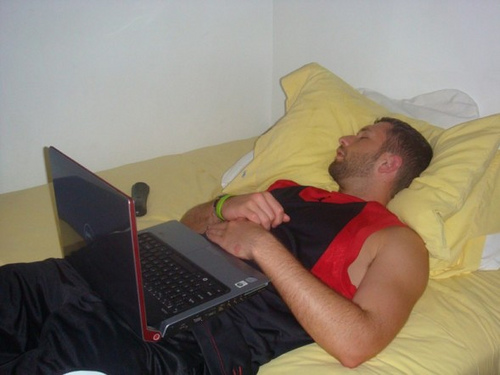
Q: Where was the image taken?
A: It was taken at the bedroom.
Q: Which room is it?
A: It is a bedroom.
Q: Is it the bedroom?
A: Yes, it is the bedroom.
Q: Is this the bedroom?
A: Yes, it is the bedroom.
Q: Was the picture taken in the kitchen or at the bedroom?
A: It was taken at the bedroom.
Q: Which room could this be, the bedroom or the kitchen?
A: It is the bedroom.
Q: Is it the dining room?
A: No, it is the bedroom.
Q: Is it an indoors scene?
A: Yes, it is indoors.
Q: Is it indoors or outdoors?
A: It is indoors.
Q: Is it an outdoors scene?
A: No, it is indoors.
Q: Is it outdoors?
A: No, it is indoors.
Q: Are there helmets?
A: No, there are no helmets.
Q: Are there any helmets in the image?
A: No, there are no helmets.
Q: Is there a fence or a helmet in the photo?
A: No, there are no helmets or fences.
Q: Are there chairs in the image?
A: No, there are no chairs.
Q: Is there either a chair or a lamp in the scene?
A: No, there are no chairs or lamps.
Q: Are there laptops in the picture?
A: Yes, there is a laptop.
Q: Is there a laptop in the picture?
A: Yes, there is a laptop.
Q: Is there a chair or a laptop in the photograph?
A: Yes, there is a laptop.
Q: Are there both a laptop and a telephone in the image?
A: No, there is a laptop but no phones.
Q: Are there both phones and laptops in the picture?
A: No, there is a laptop but no phones.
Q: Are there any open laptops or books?
A: Yes, there is an open laptop.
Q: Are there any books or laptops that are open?
A: Yes, the laptop is open.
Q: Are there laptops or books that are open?
A: Yes, the laptop is open.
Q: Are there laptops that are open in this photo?
A: Yes, there is an open laptop.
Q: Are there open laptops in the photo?
A: Yes, there is an open laptop.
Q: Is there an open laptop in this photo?
A: Yes, there is an open laptop.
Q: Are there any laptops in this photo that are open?
A: Yes, there is a laptop that is open.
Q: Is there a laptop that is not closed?
A: Yes, there is a open laptop.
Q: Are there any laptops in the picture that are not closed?
A: Yes, there is a open laptop.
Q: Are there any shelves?
A: No, there are no shelves.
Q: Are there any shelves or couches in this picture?
A: No, there are no shelves or couches.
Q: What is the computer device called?
A: The device is a laptop.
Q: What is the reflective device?
A: The device is a laptop.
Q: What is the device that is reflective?
A: The device is a laptop.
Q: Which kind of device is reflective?
A: The device is a laptop.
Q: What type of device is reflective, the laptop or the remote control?
A: The laptop is reflective.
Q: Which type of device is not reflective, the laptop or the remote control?
A: The remote control is not reflective.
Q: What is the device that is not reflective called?
A: The device is a remote control.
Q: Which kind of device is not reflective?
A: The device is a remote control.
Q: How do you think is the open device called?
A: The device is a laptop.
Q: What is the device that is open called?
A: The device is a laptop.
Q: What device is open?
A: The device is a laptop.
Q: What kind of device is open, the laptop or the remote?
A: The laptop is open.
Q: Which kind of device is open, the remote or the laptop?
A: The laptop is open.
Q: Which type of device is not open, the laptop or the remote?
A: The remote is not open.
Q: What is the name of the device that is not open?
A: The device is a remote control.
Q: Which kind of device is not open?
A: The device is a remote control.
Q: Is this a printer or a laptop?
A: This is a laptop.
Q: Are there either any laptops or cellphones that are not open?
A: No, there is a laptop but it is open.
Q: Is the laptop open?
A: Yes, the laptop is open.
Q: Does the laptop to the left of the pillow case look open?
A: Yes, the laptop is open.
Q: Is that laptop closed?
A: No, the laptop is open.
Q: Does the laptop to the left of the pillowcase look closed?
A: No, the laptop is open.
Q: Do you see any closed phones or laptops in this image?
A: No, there is a laptop but it is open.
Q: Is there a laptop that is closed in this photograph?
A: No, there is a laptop but it is open.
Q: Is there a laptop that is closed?
A: No, there is a laptop but it is open.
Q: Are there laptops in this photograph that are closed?
A: No, there is a laptop but it is open.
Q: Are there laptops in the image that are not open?
A: No, there is a laptop but it is open.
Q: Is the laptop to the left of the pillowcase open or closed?
A: The laptop computer is open.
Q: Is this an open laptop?
A: Yes, this is an open laptop.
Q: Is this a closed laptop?
A: No, this is an open laptop.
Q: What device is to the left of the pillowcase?
A: The device is a laptop.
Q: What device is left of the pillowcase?
A: The device is a laptop.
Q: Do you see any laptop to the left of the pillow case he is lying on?
A: Yes, there is a laptop to the left of the pillow case.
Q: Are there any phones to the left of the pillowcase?
A: No, there is a laptop to the left of the pillowcase.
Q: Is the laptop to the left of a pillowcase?
A: Yes, the laptop is to the left of a pillowcase.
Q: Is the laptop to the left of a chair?
A: No, the laptop is to the left of a pillowcase.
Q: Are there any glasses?
A: No, there are no glasses.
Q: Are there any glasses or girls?
A: No, there are no glasses or girls.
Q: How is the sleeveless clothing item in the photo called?
A: The clothing item is a shirt.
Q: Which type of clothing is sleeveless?
A: The clothing is a shirt.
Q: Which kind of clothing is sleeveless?
A: The clothing is a shirt.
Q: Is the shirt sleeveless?
A: Yes, the shirt is sleeveless.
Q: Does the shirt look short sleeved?
A: No, the shirt is sleeveless.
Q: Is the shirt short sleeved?
A: No, the shirt is sleeveless.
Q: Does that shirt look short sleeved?
A: No, the shirt is sleeveless.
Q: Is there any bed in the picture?
A: Yes, there is a bed.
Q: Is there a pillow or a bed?
A: Yes, there is a bed.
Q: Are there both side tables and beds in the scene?
A: No, there is a bed but no side tables.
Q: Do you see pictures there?
A: No, there are no pictures.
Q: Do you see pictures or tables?
A: No, there are no pictures or tables.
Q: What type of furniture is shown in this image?
A: The furniture is a bed.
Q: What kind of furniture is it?
A: The piece of furniture is a bed.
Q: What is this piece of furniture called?
A: This is a bed.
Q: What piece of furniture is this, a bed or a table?
A: This is a bed.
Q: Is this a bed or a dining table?
A: This is a bed.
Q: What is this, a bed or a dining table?
A: This is a bed.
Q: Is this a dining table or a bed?
A: This is a bed.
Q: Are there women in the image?
A: No, there are no women.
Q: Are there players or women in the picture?
A: No, there are no women or players.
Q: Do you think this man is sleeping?
A: Yes, the man is sleeping.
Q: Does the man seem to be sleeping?
A: Yes, the man is sleeping.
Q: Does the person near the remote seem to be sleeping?
A: Yes, the man is sleeping.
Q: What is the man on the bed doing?
A: The man is sleeping.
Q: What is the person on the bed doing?
A: The man is sleeping.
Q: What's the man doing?
A: The man is sleeping.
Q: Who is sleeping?
A: The man is sleeping.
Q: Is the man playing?
A: No, the man is sleeping.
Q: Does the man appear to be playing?
A: No, the man is sleeping.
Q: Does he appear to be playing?
A: No, the man is sleeping.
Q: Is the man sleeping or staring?
A: The man is sleeping.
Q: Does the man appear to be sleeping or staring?
A: The man is sleeping.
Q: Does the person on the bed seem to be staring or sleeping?
A: The man is sleeping.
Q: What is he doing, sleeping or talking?
A: The man is sleeping.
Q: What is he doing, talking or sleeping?
A: The man is sleeping.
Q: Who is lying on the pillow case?
A: The man is lying on the pillow case.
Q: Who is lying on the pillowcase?
A: The man is lying on the pillow case.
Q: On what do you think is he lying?
A: The man is lying on the pillow case.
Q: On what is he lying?
A: The man is lying on the pillow case.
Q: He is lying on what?
A: The man is lying on the pillow case.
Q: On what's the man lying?
A: The man is lying on the pillow case.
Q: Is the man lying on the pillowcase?
A: Yes, the man is lying on the pillowcase.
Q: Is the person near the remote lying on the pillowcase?
A: Yes, the man is lying on the pillowcase.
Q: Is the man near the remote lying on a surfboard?
A: No, the man is lying on the pillowcase.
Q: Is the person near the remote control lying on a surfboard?
A: No, the man is lying on the pillowcase.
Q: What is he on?
A: The man is on the bed.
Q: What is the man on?
A: The man is on the bed.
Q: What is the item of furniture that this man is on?
A: The piece of furniture is a bed.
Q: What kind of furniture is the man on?
A: The man is on the bed.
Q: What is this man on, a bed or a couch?
A: The man is on a bed.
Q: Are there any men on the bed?
A: Yes, there is a man on the bed.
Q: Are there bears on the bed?
A: No, there is a man on the bed.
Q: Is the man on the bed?
A: Yes, the man is on the bed.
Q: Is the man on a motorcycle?
A: No, the man is on the bed.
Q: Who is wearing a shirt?
A: The man is wearing a shirt.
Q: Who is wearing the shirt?
A: The man is wearing a shirt.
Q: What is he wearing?
A: The man is wearing a shirt.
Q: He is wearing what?
A: The man is wearing a shirt.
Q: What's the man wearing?
A: The man is wearing a shirt.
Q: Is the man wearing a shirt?
A: Yes, the man is wearing a shirt.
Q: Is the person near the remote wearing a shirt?
A: Yes, the man is wearing a shirt.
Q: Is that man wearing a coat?
A: No, the man is wearing a shirt.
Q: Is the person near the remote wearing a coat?
A: No, the man is wearing a shirt.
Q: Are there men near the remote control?
A: Yes, there is a man near the remote control.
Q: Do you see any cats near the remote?
A: No, there is a man near the remote.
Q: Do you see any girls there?
A: No, there are no girls.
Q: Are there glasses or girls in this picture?
A: No, there are no girls or glasses.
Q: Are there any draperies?
A: No, there are no draperies.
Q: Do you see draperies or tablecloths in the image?
A: No, there are no draperies or tablecloths.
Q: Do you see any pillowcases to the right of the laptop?
A: Yes, there is a pillowcase to the right of the laptop.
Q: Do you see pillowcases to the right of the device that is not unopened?
A: Yes, there is a pillowcase to the right of the laptop.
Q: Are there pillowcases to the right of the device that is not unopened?
A: Yes, there is a pillowcase to the right of the laptop.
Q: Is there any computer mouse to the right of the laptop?
A: No, there is a pillowcase to the right of the laptop.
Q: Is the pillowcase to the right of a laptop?
A: Yes, the pillowcase is to the right of a laptop.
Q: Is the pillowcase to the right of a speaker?
A: No, the pillowcase is to the right of a laptop.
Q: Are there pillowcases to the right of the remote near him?
A: Yes, there is a pillowcase to the right of the remote.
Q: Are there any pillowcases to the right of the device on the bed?
A: Yes, there is a pillowcase to the right of the remote.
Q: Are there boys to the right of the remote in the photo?
A: No, there is a pillowcase to the right of the remote.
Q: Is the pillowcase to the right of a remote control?
A: Yes, the pillowcase is to the right of a remote control.